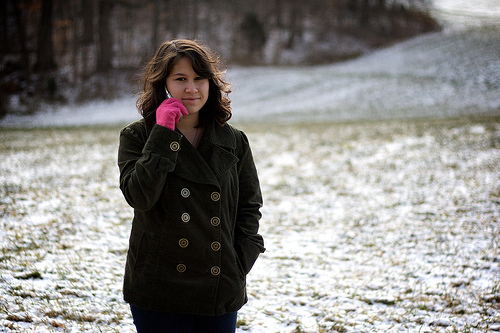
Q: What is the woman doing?
A: Talking.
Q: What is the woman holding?
A: Cellphone.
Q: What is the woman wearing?
A: Black coat.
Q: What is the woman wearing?
A: Black coat with buttons.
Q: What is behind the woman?
A: Water.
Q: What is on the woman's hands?
A: Pink gloves.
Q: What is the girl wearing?
A: A peacoat.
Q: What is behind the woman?
A: Bare trees.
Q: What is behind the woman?
A: A snow covered field.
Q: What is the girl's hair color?
A: Brown.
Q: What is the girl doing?
A: Talking on phone.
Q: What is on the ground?
A: Snow.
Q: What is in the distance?
A: Hills.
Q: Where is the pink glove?
A: On the girl's right hand.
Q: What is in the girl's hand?
A: Phone.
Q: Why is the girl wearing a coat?
A: Cold.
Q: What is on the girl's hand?
A: Glove.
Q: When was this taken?
A: Winter.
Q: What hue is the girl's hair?
A: Brown.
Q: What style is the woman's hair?
A: Curly.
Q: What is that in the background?
A: A sea of trees.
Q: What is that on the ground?
A: Some snow and grass.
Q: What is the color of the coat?
A: A darkish green.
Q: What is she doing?
A: Chatting on the phone.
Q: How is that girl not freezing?
A: By wearing a coat.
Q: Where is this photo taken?
A: Outside the woods.